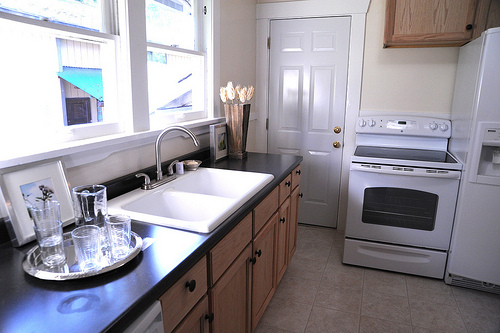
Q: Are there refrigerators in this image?
A: Yes, there is a refrigerator.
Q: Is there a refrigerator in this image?
A: Yes, there is a refrigerator.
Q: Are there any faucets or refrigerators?
A: Yes, there is a refrigerator.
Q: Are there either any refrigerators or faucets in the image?
A: Yes, there is a refrigerator.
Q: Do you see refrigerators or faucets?
A: Yes, there is a refrigerator.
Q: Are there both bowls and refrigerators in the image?
A: No, there is a refrigerator but no bowls.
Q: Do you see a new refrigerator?
A: Yes, there is a new refrigerator.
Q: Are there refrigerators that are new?
A: Yes, there is a refrigerator that is new.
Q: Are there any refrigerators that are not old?
A: Yes, there is an new refrigerator.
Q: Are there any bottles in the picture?
A: No, there are no bottles.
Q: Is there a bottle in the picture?
A: No, there are no bottles.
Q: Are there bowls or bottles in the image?
A: No, there are no bottles or bowls.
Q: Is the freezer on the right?
A: Yes, the freezer is on the right of the image.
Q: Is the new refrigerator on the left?
A: No, the refrigerator is on the right of the image.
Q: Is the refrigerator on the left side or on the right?
A: The refrigerator is on the right of the image.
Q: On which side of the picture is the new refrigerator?
A: The freezer is on the right of the image.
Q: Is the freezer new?
A: Yes, the freezer is new.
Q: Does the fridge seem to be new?
A: Yes, the fridge is new.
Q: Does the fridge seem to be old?
A: No, the fridge is new.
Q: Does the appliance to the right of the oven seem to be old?
A: No, the refrigerator is new.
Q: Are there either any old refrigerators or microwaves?
A: No, there is a refrigerator but it is new.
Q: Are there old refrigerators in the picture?
A: No, there is a refrigerator but it is new.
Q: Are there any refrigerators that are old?
A: No, there is a refrigerator but it is new.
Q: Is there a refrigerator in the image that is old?
A: No, there is a refrigerator but it is new.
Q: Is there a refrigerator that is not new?
A: No, there is a refrigerator but it is new.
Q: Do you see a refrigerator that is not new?
A: No, there is a refrigerator but it is new.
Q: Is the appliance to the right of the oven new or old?
A: The freezer is new.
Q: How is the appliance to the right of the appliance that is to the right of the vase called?
A: The appliance is a refrigerator.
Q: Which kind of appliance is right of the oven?
A: The appliance is a refrigerator.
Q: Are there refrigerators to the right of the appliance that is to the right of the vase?
A: Yes, there is a refrigerator to the right of the oven.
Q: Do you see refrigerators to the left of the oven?
A: No, the refrigerator is to the right of the oven.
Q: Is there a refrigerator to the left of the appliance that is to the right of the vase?
A: No, the refrigerator is to the right of the oven.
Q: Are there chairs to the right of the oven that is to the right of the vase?
A: No, there is a refrigerator to the right of the oven.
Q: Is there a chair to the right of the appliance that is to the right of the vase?
A: No, there is a refrigerator to the right of the oven.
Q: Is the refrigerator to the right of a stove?
A: No, the refrigerator is to the right of the oven.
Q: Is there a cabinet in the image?
A: Yes, there is a cabinet.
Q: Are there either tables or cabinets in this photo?
A: Yes, there is a cabinet.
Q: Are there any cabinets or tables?
A: Yes, there is a cabinet.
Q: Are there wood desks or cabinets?
A: Yes, there is a wood cabinet.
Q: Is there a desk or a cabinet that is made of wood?
A: Yes, the cabinet is made of wood.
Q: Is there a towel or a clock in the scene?
A: No, there are no towels or clocks.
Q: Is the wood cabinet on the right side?
A: Yes, the cabinet is on the right of the image.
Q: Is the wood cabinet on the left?
A: No, the cabinet is on the right of the image.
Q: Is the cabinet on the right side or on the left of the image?
A: The cabinet is on the right of the image.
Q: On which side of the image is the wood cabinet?
A: The cabinet is on the right of the image.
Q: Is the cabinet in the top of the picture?
A: Yes, the cabinet is in the top of the image.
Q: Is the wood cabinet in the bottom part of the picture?
A: No, the cabinet is in the top of the image.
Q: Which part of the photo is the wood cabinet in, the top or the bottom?
A: The cabinet is in the top of the image.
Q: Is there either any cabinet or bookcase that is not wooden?
A: No, there is a cabinet but it is wooden.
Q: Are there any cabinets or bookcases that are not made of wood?
A: No, there is a cabinet but it is made of wood.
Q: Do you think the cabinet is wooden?
A: Yes, the cabinet is wooden.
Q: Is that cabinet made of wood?
A: Yes, the cabinet is made of wood.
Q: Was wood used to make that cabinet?
A: Yes, the cabinet is made of wood.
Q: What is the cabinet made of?
A: The cabinet is made of wood.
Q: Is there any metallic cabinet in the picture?
A: No, there is a cabinet but it is wooden.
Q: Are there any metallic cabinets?
A: No, there is a cabinet but it is wooden.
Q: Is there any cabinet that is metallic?
A: No, there is a cabinet but it is wooden.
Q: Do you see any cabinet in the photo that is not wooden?
A: No, there is a cabinet but it is wooden.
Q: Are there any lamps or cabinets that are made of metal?
A: No, there is a cabinet but it is made of wood.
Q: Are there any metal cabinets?
A: No, there is a cabinet but it is made of wood.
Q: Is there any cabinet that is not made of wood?
A: No, there is a cabinet but it is made of wood.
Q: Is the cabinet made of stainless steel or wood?
A: The cabinet is made of wood.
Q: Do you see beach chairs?
A: No, there are no beach chairs.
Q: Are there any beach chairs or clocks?
A: No, there are no beach chairs or clocks.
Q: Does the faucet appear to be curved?
A: Yes, the faucet is curved.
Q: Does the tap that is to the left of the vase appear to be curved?
A: Yes, the tap is curved.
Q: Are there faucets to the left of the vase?
A: Yes, there is a faucet to the left of the vase.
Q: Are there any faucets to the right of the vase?
A: No, the faucet is to the left of the vase.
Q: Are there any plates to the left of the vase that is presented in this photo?
A: No, there is a faucet to the left of the vase.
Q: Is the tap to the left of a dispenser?
A: No, the tap is to the left of the vase.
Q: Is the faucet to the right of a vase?
A: No, the faucet is to the left of a vase.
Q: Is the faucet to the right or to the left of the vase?
A: The faucet is to the left of the vase.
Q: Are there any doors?
A: Yes, there is a door.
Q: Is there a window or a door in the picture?
A: Yes, there is a door.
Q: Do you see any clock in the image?
A: No, there are no clocks.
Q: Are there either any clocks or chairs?
A: No, there are no clocks or chairs.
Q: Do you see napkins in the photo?
A: No, there are no napkins.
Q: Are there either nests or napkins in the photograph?
A: No, there are no napkins or nests.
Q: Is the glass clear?
A: Yes, the glass is clear.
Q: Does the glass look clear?
A: Yes, the glass is clear.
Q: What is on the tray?
A: The glass is on the tray.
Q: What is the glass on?
A: The glass is on the tray.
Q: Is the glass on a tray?
A: Yes, the glass is on a tray.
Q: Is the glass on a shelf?
A: No, the glass is on a tray.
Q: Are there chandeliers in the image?
A: No, there are no chandeliers.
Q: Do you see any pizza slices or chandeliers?
A: No, there are no chandeliers or pizza slices.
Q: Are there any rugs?
A: No, there are no rugs.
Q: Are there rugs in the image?
A: No, there are no rugs.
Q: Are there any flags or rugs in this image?
A: No, there are no rugs or flags.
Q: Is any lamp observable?
A: No, there are no lamps.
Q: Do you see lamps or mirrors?
A: No, there are no lamps or mirrors.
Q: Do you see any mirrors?
A: No, there are no mirrors.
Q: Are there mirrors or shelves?
A: No, there are no mirrors or shelves.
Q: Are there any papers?
A: No, there are no papers.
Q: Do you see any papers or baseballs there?
A: No, there are no papers or baseballs.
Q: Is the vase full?
A: Yes, the vase is full.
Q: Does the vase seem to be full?
A: Yes, the vase is full.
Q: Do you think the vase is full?
A: Yes, the vase is full.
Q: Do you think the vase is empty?
A: No, the vase is full.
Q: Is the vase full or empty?
A: The vase is full.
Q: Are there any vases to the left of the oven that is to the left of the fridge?
A: Yes, there is a vase to the left of the oven.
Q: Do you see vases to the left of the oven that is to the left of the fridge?
A: Yes, there is a vase to the left of the oven.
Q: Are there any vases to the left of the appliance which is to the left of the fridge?
A: Yes, there is a vase to the left of the oven.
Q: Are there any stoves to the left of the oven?
A: No, there is a vase to the left of the oven.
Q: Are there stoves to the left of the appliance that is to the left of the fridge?
A: No, there is a vase to the left of the oven.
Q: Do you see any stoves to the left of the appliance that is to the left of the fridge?
A: No, there is a vase to the left of the oven.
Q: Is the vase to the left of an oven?
A: Yes, the vase is to the left of an oven.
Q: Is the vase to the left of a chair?
A: No, the vase is to the left of an oven.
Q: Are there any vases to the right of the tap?
A: Yes, there is a vase to the right of the tap.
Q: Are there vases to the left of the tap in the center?
A: No, the vase is to the right of the faucet.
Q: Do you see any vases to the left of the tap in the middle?
A: No, the vase is to the right of the faucet.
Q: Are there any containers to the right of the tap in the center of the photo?
A: No, there is a vase to the right of the tap.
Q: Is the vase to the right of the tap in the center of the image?
A: Yes, the vase is to the right of the faucet.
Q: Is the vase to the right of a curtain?
A: No, the vase is to the right of the faucet.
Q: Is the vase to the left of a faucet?
A: No, the vase is to the right of a faucet.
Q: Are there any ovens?
A: Yes, there is an oven.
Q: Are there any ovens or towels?
A: Yes, there is an oven.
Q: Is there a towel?
A: No, there are no towels.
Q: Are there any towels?
A: No, there are no towels.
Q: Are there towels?
A: No, there are no towels.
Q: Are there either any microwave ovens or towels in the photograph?
A: No, there are no towels or microwave ovens.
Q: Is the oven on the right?
A: Yes, the oven is on the right of the image.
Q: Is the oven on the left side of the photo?
A: No, the oven is on the right of the image.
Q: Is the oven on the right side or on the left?
A: The oven is on the right of the image.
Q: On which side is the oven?
A: The oven is on the right of the image.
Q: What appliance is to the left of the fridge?
A: The appliance is an oven.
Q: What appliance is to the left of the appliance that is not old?
A: The appliance is an oven.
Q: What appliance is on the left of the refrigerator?
A: The appliance is an oven.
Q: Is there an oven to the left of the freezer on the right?
A: Yes, there is an oven to the left of the fridge.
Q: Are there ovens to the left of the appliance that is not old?
A: Yes, there is an oven to the left of the fridge.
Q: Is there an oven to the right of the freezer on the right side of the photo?
A: No, the oven is to the left of the freezer.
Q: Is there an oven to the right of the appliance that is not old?
A: No, the oven is to the left of the freezer.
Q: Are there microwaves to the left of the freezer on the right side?
A: No, there is an oven to the left of the fridge.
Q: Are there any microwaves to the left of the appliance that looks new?
A: No, there is an oven to the left of the fridge.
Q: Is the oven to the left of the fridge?
A: Yes, the oven is to the left of the fridge.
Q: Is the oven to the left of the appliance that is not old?
A: Yes, the oven is to the left of the fridge.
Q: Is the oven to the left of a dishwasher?
A: No, the oven is to the left of the fridge.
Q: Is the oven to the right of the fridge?
A: No, the oven is to the left of the fridge.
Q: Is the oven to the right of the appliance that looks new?
A: No, the oven is to the left of the fridge.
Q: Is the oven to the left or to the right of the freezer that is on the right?
A: The oven is to the left of the refrigerator.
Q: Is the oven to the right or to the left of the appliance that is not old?
A: The oven is to the left of the refrigerator.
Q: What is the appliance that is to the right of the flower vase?
A: The appliance is an oven.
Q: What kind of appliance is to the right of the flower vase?
A: The appliance is an oven.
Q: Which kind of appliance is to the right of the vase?
A: The appliance is an oven.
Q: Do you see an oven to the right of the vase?
A: Yes, there is an oven to the right of the vase.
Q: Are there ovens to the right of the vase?
A: Yes, there is an oven to the right of the vase.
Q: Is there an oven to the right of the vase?
A: Yes, there is an oven to the right of the vase.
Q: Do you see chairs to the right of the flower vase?
A: No, there is an oven to the right of the vase.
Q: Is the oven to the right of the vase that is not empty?
A: Yes, the oven is to the right of the vase.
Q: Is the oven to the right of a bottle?
A: No, the oven is to the right of the vase.